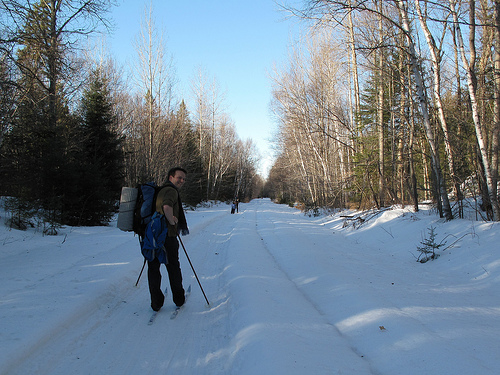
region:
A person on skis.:
[97, 140, 222, 325]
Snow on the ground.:
[250, 230, 380, 361]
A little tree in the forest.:
[405, 225, 445, 265]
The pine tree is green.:
[50, 70, 120, 215]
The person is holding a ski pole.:
[165, 220, 225, 315]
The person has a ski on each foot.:
[140, 275, 200, 330]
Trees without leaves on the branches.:
[275, 0, 375, 215]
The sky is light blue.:
[175, 5, 280, 55]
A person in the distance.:
[225, 191, 245, 211]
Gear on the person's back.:
[112, 178, 158, 234]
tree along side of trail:
[85, 73, 127, 212]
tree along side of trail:
[23, 88, 82, 233]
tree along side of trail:
[181, 129, 213, 197]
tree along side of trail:
[203, 130, 230, 196]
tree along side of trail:
[220, 139, 244, 204]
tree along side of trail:
[291, 103, 332, 208]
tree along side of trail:
[307, 122, 344, 215]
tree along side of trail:
[356, 100, 408, 210]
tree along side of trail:
[413, 103, 459, 215]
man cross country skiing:
[138, 154, 215, 325]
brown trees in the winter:
[341, 11, 399, 128]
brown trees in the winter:
[303, 89, 352, 204]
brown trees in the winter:
[387, 41, 444, 155]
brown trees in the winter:
[441, 51, 488, 203]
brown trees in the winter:
[16, 29, 74, 175]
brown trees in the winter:
[35, 86, 96, 173]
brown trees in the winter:
[193, 124, 226, 166]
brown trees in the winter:
[103, 98, 150, 128]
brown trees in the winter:
[268, 171, 402, 199]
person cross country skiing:
[117, 138, 218, 315]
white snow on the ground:
[23, 233, 83, 290]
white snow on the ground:
[71, 257, 117, 310]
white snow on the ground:
[30, 283, 107, 346]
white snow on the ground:
[211, 211, 303, 261]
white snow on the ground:
[241, 254, 345, 339]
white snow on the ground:
[289, 284, 366, 342]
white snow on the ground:
[366, 279, 445, 336]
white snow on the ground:
[450, 237, 486, 302]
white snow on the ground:
[306, 243, 407, 311]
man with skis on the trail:
[121, 158, 249, 330]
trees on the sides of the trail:
[44, 125, 87, 223]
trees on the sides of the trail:
[400, 108, 452, 213]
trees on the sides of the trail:
[441, 45, 496, 215]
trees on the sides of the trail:
[368, 107, 385, 207]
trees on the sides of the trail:
[351, 112, 377, 205]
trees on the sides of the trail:
[331, 105, 352, 202]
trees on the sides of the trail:
[182, 140, 204, 190]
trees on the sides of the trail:
[31, 125, 56, 231]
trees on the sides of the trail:
[22, 128, 42, 223]